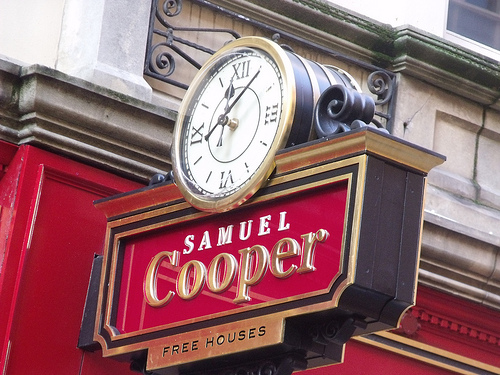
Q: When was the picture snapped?
A: Daytime.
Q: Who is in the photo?
A: Nobody.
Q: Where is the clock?
A: On the sign.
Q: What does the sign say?
A: Samuel Cooper Free Houses.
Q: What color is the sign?
A: Red with gold.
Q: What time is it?
A: 12:10.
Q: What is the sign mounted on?
A: The building.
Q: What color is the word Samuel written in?
A: White.